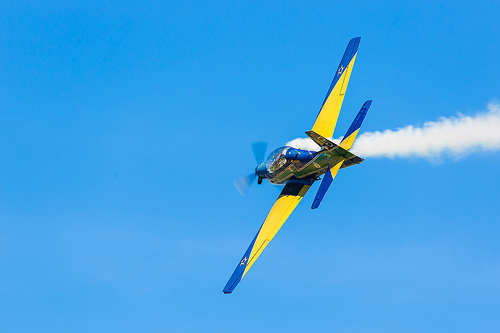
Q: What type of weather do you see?
A: It is clear.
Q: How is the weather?
A: It is clear.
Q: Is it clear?
A: Yes, it is clear.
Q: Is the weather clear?
A: Yes, it is clear.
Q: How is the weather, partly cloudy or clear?
A: It is clear.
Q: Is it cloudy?
A: No, it is clear.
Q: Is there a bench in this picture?
A: No, there are no benches.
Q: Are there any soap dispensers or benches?
A: No, there are no benches or soap dispensers.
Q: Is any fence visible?
A: No, there are no fences.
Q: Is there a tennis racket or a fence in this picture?
A: No, there are no fences or rackets.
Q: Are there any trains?
A: No, there are no trains.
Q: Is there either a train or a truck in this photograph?
A: No, there are no trains or trucks.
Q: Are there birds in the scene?
A: No, there are no birds.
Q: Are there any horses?
A: No, there are no horses.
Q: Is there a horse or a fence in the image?
A: No, there are no horses or fences.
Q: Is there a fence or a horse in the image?
A: No, there are no horses or fences.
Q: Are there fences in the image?
A: No, there are no fences.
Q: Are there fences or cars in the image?
A: No, there are no fences or cars.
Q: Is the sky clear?
A: Yes, the sky is clear.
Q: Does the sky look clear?
A: Yes, the sky is clear.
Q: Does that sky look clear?
A: Yes, the sky is clear.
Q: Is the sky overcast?
A: No, the sky is clear.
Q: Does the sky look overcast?
A: No, the sky is clear.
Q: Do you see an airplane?
A: Yes, there is an airplane.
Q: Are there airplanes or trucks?
A: Yes, there is an airplane.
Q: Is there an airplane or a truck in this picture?
A: Yes, there is an airplane.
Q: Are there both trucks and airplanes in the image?
A: No, there is an airplane but no trucks.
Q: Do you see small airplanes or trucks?
A: Yes, there is a small airplane.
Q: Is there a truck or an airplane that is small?
A: Yes, the airplane is small.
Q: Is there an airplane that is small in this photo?
A: Yes, there is a small airplane.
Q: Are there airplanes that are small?
A: Yes, there is an airplane that is small.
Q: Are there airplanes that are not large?
A: Yes, there is a small airplane.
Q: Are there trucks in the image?
A: No, there are no trucks.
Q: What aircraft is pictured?
A: The aircraft is an airplane.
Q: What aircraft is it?
A: The aircraft is an airplane.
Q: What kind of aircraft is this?
A: This is an airplane.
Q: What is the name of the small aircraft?
A: The aircraft is an airplane.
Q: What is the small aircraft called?
A: The aircraft is an airplane.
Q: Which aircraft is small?
A: The aircraft is an airplane.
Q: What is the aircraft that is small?
A: The aircraft is an airplane.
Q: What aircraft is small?
A: The aircraft is an airplane.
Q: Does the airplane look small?
A: Yes, the airplane is small.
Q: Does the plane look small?
A: Yes, the plane is small.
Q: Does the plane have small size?
A: Yes, the plane is small.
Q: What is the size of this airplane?
A: The airplane is small.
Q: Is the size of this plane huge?
A: No, the plane is small.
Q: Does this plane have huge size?
A: No, the plane is small.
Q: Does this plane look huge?
A: No, the plane is small.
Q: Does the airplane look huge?
A: No, the airplane is small.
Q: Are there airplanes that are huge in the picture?
A: No, there is an airplane but it is small.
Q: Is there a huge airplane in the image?
A: No, there is an airplane but it is small.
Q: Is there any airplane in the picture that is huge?
A: No, there is an airplane but it is small.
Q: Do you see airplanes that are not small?
A: No, there is an airplane but it is small.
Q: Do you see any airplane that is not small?
A: No, there is an airplane but it is small.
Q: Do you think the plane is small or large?
A: The plane is small.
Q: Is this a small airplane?
A: Yes, this is a small airplane.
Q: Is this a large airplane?
A: No, this is a small airplane.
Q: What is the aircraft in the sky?
A: The aircraft is an airplane.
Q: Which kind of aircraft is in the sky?
A: The aircraft is an airplane.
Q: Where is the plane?
A: The plane is in the sky.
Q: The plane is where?
A: The plane is in the sky.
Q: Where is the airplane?
A: The plane is in the sky.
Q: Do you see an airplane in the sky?
A: Yes, there is an airplane in the sky.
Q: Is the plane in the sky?
A: Yes, the plane is in the sky.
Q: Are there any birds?
A: No, there are no birds.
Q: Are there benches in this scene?
A: No, there are no benches.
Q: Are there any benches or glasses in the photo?
A: No, there are no benches or glasses.